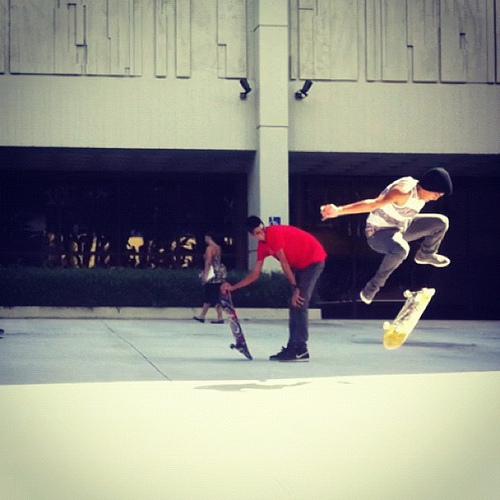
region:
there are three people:
[136, 125, 488, 414]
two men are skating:
[196, 156, 485, 348]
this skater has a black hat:
[299, 144, 493, 274]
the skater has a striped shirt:
[363, 182, 445, 252]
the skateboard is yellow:
[332, 186, 460, 387]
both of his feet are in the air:
[337, 209, 475, 370]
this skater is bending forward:
[195, 188, 342, 390]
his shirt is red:
[187, 192, 348, 383]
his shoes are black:
[241, 330, 314, 368]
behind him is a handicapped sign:
[243, 199, 290, 246]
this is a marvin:
[420, 167, 448, 190]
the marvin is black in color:
[422, 171, 445, 183]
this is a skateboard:
[377, 286, 437, 348]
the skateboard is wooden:
[401, 300, 418, 317]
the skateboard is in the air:
[371, 289, 439, 344]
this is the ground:
[38, 323, 185, 460]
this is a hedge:
[50, 272, 180, 307]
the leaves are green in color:
[137, 273, 177, 298]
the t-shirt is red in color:
[273, 234, 300, 251]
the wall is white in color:
[255, 128, 285, 151]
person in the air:
[350, 156, 470, 359]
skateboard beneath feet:
[370, 276, 437, 382]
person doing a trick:
[340, 176, 465, 362]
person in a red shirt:
[230, 197, 325, 317]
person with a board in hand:
[195, 277, 256, 367]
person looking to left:
[216, 200, 327, 330]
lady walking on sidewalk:
[171, 228, 226, 326]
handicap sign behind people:
[268, 205, 287, 230]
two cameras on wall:
[206, 48, 331, 128]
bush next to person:
[69, 261, 154, 309]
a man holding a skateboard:
[199, 143, 467, 388]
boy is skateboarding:
[316, 153, 497, 340]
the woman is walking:
[174, 211, 257, 346]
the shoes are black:
[244, 333, 325, 385]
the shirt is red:
[234, 219, 354, 281]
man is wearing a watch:
[265, 276, 325, 296]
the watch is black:
[272, 276, 307, 298]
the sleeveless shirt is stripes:
[347, 162, 434, 234]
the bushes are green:
[52, 266, 165, 300]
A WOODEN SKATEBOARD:
[371, 282, 434, 355]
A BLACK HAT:
[410, 166, 455, 203]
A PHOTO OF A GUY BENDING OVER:
[215, 211, 327, 372]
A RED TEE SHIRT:
[251, 220, 336, 275]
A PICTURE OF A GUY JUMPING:
[318, 157, 473, 361]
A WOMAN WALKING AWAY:
[189, 227, 231, 331]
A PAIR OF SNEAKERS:
[262, 339, 315, 367]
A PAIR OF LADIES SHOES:
[185, 311, 231, 328]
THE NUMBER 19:
[256, 208, 294, 235]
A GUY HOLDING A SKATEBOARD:
[201, 212, 331, 365]